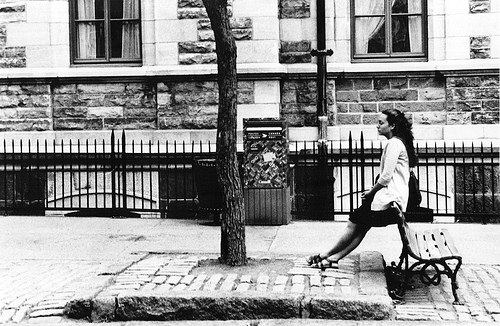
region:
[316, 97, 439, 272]
a lady seate on a bench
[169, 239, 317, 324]
the floor is made of concrete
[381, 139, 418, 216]
sweater is whute incolor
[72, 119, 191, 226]
the fence is made of metals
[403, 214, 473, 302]
the bench is wooden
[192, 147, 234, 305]
tree is beside the bench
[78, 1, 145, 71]
the curtains are open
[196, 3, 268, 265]
it is a tree in center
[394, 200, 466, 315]
it is a chair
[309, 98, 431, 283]
lady standing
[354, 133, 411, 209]
lady wearing white shirt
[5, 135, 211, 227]
it is a side gate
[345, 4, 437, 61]
it is a window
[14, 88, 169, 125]
it is stones in the building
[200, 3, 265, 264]
this is a tree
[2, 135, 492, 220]
this is a gate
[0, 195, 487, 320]
this is a floor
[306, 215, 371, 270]
these are legs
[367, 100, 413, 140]
this is a person`s head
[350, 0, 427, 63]
this is a window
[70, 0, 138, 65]
this is a window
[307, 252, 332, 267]
these are ladies shoes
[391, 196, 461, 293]
this is a sitting bench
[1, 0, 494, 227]
this is a building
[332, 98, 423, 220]
this is a lady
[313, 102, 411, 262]
the lady is motionless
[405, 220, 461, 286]
this is a bench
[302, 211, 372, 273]
these are the legs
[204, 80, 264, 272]
this is a tree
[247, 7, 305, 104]
this is a house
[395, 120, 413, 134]
this is the hair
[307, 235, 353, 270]
the legs are crossed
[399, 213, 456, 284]
the bench is empty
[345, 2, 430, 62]
window on house right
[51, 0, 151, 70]
window on house left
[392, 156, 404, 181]
woman with white shirt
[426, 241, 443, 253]
empty bench behind woman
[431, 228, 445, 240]
brown wood on bench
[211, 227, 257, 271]
bottom of tall tree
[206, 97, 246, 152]
middle of tall tree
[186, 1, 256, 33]
top of tall tree